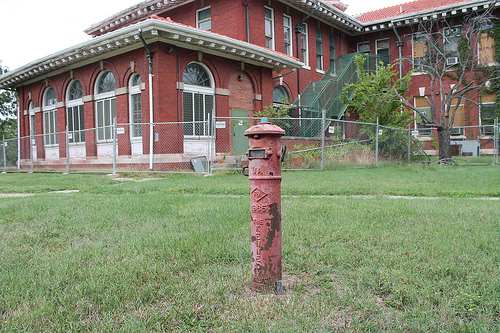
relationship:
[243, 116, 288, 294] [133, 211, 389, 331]
bollard on grass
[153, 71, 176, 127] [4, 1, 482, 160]
bricks in building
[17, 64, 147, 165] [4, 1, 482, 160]
doors on building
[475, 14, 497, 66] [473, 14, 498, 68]
window on window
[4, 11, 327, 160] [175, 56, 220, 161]
house has door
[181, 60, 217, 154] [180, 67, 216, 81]
door with tops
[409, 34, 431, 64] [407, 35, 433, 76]
plywood covering windows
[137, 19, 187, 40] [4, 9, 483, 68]
effects on roof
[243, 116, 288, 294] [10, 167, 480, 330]
bollard in grass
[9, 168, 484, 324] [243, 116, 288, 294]
area beneath bollard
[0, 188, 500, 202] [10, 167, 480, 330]
path in grass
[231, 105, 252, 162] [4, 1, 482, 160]
door on building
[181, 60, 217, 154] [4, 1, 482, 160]
door on building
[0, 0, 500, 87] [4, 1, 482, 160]
roof of building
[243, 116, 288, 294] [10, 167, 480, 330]
bollard of grass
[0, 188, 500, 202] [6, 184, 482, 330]
path through grass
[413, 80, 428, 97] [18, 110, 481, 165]
sign on fence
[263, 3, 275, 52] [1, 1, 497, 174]
window on building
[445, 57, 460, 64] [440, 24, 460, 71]
unit in window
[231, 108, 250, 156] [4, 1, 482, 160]
door on building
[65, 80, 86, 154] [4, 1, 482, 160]
window on building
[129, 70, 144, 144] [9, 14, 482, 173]
window on building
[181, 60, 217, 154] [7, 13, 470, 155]
door on building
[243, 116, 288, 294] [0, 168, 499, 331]
bollard in area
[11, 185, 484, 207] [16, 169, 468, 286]
path in yard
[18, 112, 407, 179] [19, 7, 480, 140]
fence in front of building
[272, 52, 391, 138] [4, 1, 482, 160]
staircase on building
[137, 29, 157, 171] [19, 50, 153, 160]
drain on wall